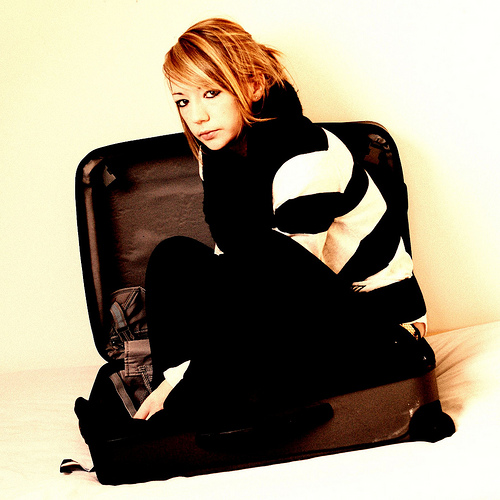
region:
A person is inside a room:
[50, 10, 483, 445]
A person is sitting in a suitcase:
[35, 20, 487, 450]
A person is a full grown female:
[40, 11, 460, 447]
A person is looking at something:
[40, 20, 485, 456]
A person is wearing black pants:
[55, 15, 493, 455]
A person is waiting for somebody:
[52, 7, 472, 432]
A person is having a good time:
[50, 5, 480, 465]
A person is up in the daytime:
[35, 11, 475, 461]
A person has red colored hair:
[55, 0, 490, 431]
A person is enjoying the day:
[71, 1, 476, 496]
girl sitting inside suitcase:
[68, 15, 458, 481]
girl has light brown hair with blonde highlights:
[155, 17, 289, 160]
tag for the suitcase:
[52, 451, 94, 481]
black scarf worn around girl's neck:
[181, 89, 297, 242]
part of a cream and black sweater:
[260, 127, 427, 319]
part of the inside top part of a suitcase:
[64, 131, 152, 331]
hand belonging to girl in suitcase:
[129, 371, 176, 425]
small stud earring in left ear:
[247, 90, 262, 102]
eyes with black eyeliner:
[172, 91, 230, 108]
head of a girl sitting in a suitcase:
[162, 22, 289, 150]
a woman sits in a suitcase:
[55, 12, 445, 430]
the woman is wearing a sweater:
[198, 80, 435, 351]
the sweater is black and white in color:
[198, 78, 430, 335]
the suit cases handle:
[178, 400, 352, 457]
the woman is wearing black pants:
[147, 226, 422, 432]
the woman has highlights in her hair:
[165, 11, 306, 121]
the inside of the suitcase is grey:
[90, 171, 215, 261]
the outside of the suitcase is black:
[86, 406, 171, 476]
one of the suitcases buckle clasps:
[93, 161, 123, 196]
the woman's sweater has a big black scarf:
[204, 98, 287, 240]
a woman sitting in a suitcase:
[55, 15, 455, 490]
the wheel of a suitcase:
[416, 405, 459, 446]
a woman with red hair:
[162, 16, 302, 163]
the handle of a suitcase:
[195, 402, 334, 451]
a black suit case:
[59, 119, 457, 488]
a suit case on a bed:
[2, 119, 498, 495]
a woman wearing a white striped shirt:
[197, 115, 429, 342]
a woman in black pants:
[66, 235, 429, 437]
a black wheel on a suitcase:
[411, 407, 459, 449]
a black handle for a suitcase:
[189, 401, 344, 448]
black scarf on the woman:
[201, 78, 303, 253]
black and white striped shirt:
[194, 120, 431, 333]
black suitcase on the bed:
[69, 118, 458, 486]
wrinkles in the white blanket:
[430, 340, 467, 417]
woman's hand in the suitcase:
[130, 377, 172, 421]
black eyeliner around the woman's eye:
[176, 95, 189, 107]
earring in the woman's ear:
[253, 92, 260, 101]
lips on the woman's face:
[195, 127, 222, 140]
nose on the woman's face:
[188, 93, 211, 125]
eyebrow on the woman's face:
[170, 89, 186, 96]